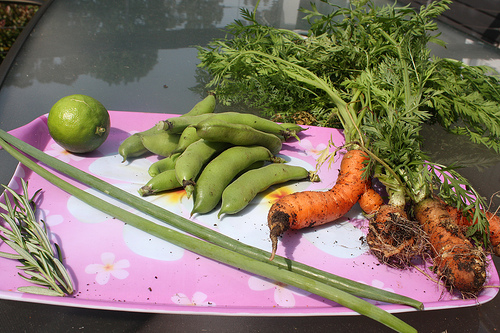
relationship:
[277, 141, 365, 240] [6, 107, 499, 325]
carrot on plate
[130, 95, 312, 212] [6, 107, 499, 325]
beans on plate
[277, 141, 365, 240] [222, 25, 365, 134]
carrot with leaves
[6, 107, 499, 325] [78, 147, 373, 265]
plate has flower design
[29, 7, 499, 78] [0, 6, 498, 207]
shadow on ground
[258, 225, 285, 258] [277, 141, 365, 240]
roots of carrot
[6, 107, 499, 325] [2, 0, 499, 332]
plate on a table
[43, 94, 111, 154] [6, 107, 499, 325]
lime on plate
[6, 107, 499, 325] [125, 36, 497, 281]
plate with vegetables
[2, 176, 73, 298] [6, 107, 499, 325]
herb on plate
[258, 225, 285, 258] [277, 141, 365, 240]
roots on carrot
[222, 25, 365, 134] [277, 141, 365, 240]
leaves on carrot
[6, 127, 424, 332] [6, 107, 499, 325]
vegetable on plate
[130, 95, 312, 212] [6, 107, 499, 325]
beans are on plate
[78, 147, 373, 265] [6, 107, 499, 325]
flower design on plate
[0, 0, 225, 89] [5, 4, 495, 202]
shadow on surface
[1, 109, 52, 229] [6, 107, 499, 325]
side of plate